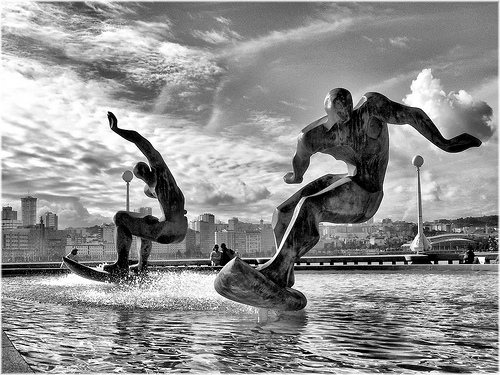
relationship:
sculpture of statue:
[206, 226, 324, 312] [55, 111, 188, 285]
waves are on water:
[133, 255, 205, 303] [33, 312, 88, 351]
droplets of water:
[156, 287, 180, 305] [33, 312, 88, 351]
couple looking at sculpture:
[201, 238, 234, 268] [206, 226, 324, 312]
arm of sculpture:
[371, 95, 474, 148] [206, 226, 324, 312]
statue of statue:
[119, 125, 170, 255] [55, 111, 188, 285]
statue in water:
[119, 125, 170, 255] [33, 312, 88, 351]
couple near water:
[201, 238, 234, 268] [33, 312, 88, 351]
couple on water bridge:
[201, 238, 234, 268] [355, 247, 414, 262]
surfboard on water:
[204, 258, 309, 309] [33, 312, 88, 351]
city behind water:
[0, 199, 106, 254] [33, 312, 88, 351]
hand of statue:
[426, 127, 476, 151] [55, 111, 188, 285]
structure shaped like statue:
[402, 149, 433, 250] [55, 111, 188, 285]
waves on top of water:
[133, 255, 205, 303] [33, 312, 88, 351]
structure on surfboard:
[402, 149, 433, 250] [204, 258, 309, 309]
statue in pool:
[119, 125, 170, 255] [283, 243, 406, 347]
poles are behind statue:
[107, 177, 134, 205] [119, 125, 170, 255]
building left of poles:
[8, 198, 80, 255] [107, 177, 134, 205]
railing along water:
[13, 256, 41, 278] [33, 312, 88, 351]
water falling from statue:
[33, 312, 88, 351] [119, 125, 170, 255]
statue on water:
[119, 125, 170, 255] [33, 312, 88, 351]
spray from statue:
[139, 274, 163, 296] [119, 125, 170, 255]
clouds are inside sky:
[96, 32, 151, 71] [290, 39, 335, 61]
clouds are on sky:
[96, 32, 151, 71] [290, 39, 335, 61]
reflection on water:
[161, 278, 232, 326] [33, 312, 88, 351]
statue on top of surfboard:
[119, 125, 170, 255] [204, 258, 309, 309]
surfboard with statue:
[204, 258, 309, 309] [119, 125, 170, 255]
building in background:
[8, 198, 80, 255] [8, 179, 447, 277]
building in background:
[8, 198, 80, 255] [10, 189, 368, 269]